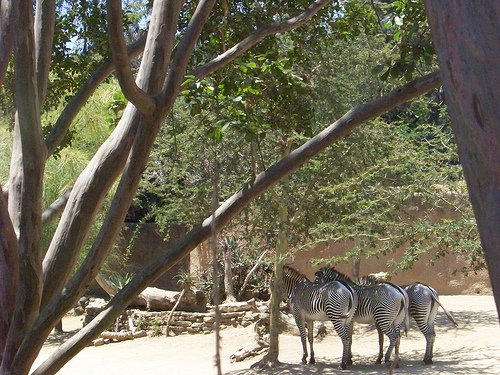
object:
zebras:
[312, 264, 410, 363]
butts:
[327, 283, 355, 315]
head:
[273, 269, 291, 300]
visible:
[129, 275, 323, 339]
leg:
[334, 291, 350, 364]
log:
[144, 285, 208, 314]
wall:
[117, 307, 187, 332]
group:
[280, 264, 356, 364]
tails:
[429, 290, 460, 325]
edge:
[186, 298, 215, 313]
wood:
[160, 245, 177, 261]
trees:
[212, 60, 357, 364]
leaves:
[260, 76, 277, 93]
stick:
[210, 213, 224, 370]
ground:
[140, 343, 272, 362]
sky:
[67, 5, 151, 56]